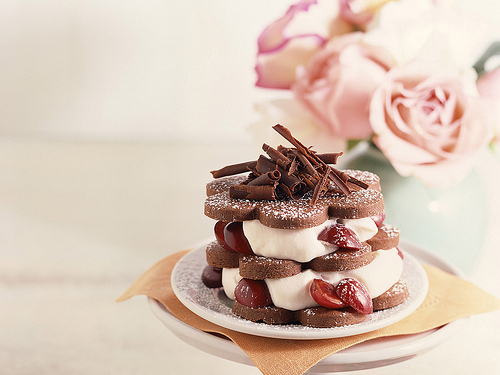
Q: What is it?
A: Dessert.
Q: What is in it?
A: Cookies and cream.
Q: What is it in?
A: A plate.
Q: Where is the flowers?
A: Next to the dessert.